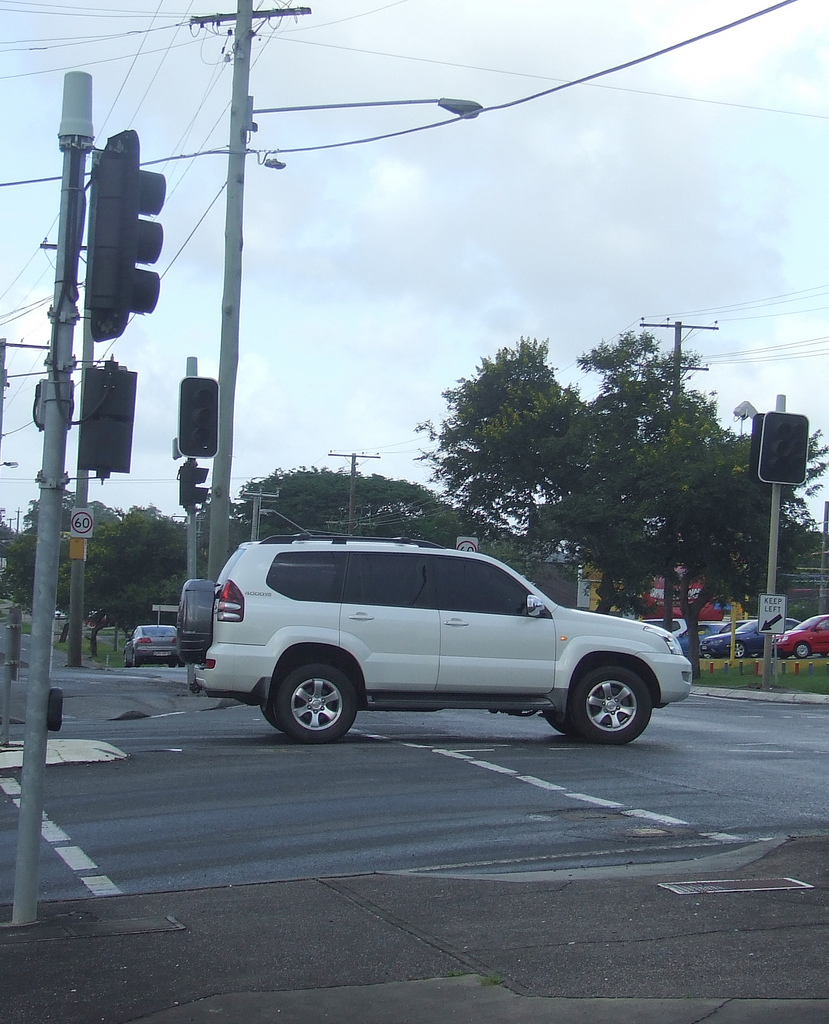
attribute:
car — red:
[777, 616, 826, 659]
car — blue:
[700, 615, 800, 654]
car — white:
[173, 537, 691, 748]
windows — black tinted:
[269, 549, 547, 619]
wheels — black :
[265, 660, 658, 751]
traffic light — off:
[749, 408, 809, 486]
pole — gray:
[13, 65, 97, 924]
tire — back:
[271, 657, 356, 747]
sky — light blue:
[363, 72, 705, 390]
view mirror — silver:
[508, 578, 560, 623]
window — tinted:
[277, 548, 521, 641]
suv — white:
[166, 517, 728, 791]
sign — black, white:
[752, 587, 791, 650]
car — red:
[760, 607, 827, 667]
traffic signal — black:
[752, 404, 818, 498]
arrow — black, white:
[752, 610, 791, 637]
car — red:
[775, 607, 820, 655]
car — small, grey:
[121, 612, 200, 673]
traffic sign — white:
[57, 497, 105, 555]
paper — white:
[137, 731, 200, 773]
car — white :
[191, 529, 701, 765]